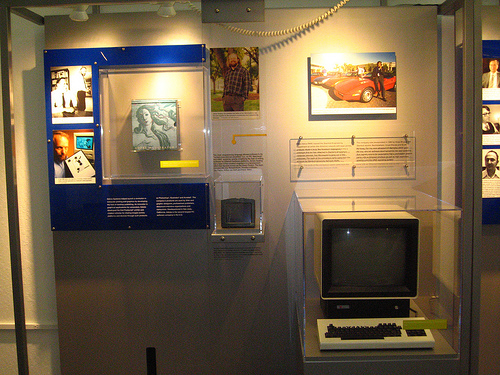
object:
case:
[98, 64, 214, 183]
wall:
[46, 11, 453, 375]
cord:
[231, 134, 268, 145]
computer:
[303, 210, 439, 355]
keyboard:
[315, 316, 439, 352]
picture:
[49, 65, 96, 123]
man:
[220, 53, 251, 112]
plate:
[220, 196, 257, 229]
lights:
[67, 5, 92, 24]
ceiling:
[44, 0, 439, 26]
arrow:
[231, 134, 267, 145]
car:
[334, 72, 397, 103]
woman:
[133, 105, 177, 151]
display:
[103, 194, 197, 220]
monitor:
[330, 228, 412, 291]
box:
[290, 138, 415, 181]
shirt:
[222, 64, 251, 98]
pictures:
[52, 128, 96, 185]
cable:
[182, 0, 351, 38]